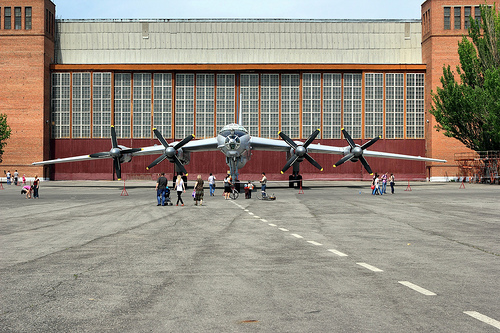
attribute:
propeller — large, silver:
[88, 122, 142, 180]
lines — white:
[323, 237, 443, 329]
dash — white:
[262, 217, 322, 255]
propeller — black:
[271, 124, 304, 156]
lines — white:
[261, 210, 464, 332]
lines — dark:
[135, 194, 257, 316]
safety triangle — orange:
[401, 179, 412, 190]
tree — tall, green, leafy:
[431, 22, 499, 179]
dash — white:
[289, 227, 425, 242]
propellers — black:
[87, 125, 379, 182]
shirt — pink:
[21, 183, 36, 195]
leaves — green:
[426, 3, 498, 154]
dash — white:
[222, 200, 442, 301]